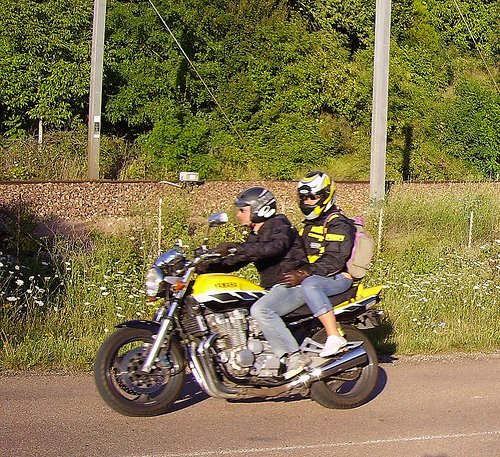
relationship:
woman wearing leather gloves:
[299, 171, 376, 378] [278, 269, 306, 286]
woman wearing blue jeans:
[299, 171, 376, 378] [251, 272, 351, 357]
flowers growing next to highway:
[7, 212, 498, 346] [0, 352, 500, 454]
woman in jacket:
[299, 171, 376, 378] [294, 216, 356, 272]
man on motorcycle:
[189, 187, 310, 380] [93, 210, 393, 416]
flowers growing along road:
[7, 212, 498, 346] [3, 352, 480, 453]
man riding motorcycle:
[189, 187, 310, 380] [93, 210, 393, 416]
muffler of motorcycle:
[185, 330, 366, 396] [93, 210, 393, 416]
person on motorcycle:
[190, 186, 316, 381] [89, 169, 387, 411]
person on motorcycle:
[280, 169, 356, 357] [89, 169, 387, 411]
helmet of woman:
[295, 170, 334, 221] [299, 171, 376, 378]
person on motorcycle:
[190, 186, 316, 381] [93, 210, 393, 416]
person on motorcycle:
[280, 169, 356, 357] [93, 210, 393, 416]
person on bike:
[280, 169, 356, 357] [94, 209, 386, 409]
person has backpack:
[280, 169, 356, 357] [324, 209, 372, 279]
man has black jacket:
[189, 187, 310, 380] [218, 219, 302, 283]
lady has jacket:
[288, 170, 356, 356] [294, 207, 350, 274]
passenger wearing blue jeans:
[294, 172, 358, 358] [253, 280, 305, 344]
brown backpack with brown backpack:
[348, 215, 373, 279] [348, 215, 373, 279]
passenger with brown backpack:
[294, 172, 358, 358] [348, 215, 373, 279]